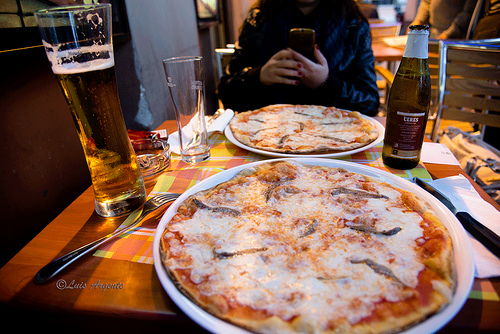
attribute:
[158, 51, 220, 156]
glass — empty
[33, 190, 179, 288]
fork — turned over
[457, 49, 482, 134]
chair — metal, wooden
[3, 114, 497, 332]
table — brown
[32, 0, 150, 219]
glass — nearly-full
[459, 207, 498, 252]
handle — black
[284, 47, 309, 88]
nail polish — red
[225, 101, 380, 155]
pizza — vegetarian, large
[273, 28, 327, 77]
cell phone — black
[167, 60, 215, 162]
glass — empty, clear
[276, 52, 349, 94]
phone — cell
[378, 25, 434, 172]
bottle — beer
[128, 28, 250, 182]
beer glass — empty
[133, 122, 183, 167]
ash tray — round 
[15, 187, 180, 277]
fork — upside down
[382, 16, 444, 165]
bottle — open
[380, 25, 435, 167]
beer bottle — empty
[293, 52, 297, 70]
nails — painted, red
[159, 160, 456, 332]
pizza — one, vegetarian, large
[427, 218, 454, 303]
crust — brown 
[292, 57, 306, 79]
nail polish — dark, red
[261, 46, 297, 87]
hand — both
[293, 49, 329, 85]
hand — both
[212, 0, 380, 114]
coat — blue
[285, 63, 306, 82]
polish — red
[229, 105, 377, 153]
pizza — one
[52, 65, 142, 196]
beer — amber, colored